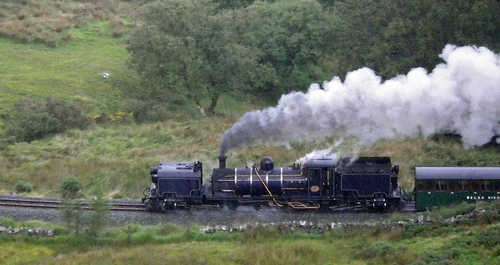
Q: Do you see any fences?
A: Yes, there is a fence.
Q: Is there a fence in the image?
A: Yes, there is a fence.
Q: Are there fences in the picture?
A: Yes, there is a fence.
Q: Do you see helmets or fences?
A: Yes, there is a fence.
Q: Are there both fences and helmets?
A: No, there is a fence but no helmets.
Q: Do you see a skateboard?
A: No, there are no skateboards.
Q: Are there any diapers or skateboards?
A: No, there are no skateboards or diapers.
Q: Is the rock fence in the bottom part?
A: Yes, the fence is in the bottom of the image.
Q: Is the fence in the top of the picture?
A: No, the fence is in the bottom of the image.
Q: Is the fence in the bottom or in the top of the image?
A: The fence is in the bottom of the image.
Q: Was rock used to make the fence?
A: Yes, the fence is made of rock.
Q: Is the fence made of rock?
A: Yes, the fence is made of rock.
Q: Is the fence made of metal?
A: No, the fence is made of rock.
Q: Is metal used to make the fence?
A: No, the fence is made of rock.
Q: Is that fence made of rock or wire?
A: The fence is made of rock.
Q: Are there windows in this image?
A: Yes, there are windows.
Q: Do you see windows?
A: Yes, there are windows.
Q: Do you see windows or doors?
A: Yes, there are windows.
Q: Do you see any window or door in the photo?
A: Yes, there are windows.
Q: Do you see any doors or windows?
A: Yes, there are windows.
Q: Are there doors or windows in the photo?
A: Yes, there are windows.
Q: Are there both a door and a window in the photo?
A: Yes, there are both a window and a door.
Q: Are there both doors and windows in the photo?
A: Yes, there are both windows and a door.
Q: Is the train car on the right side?
A: Yes, the train car is on the right of the image.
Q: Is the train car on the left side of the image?
A: No, the train car is on the right of the image.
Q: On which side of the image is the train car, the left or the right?
A: The train car is on the right of the image.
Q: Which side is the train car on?
A: The train car is on the right of the image.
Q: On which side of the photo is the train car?
A: The train car is on the right of the image.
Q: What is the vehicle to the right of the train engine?
A: The vehicle is a train car.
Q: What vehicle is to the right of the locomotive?
A: The vehicle is a train car.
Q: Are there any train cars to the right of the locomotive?
A: Yes, there is a train car to the right of the locomotive.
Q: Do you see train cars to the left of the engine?
A: No, the train car is to the right of the engine.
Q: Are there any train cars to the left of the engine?
A: No, the train car is to the right of the engine.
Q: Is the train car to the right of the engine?
A: Yes, the train car is to the right of the engine.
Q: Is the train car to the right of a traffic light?
A: No, the train car is to the right of the engine.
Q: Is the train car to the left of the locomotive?
A: No, the train car is to the right of the locomotive.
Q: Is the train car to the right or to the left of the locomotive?
A: The train car is to the right of the locomotive.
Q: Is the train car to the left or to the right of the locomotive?
A: The train car is to the right of the locomotive.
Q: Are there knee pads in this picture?
A: No, there are no knee pads.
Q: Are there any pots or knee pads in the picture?
A: No, there are no knee pads or pots.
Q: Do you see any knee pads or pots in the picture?
A: No, there are no knee pads or pots.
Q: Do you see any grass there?
A: Yes, there is grass.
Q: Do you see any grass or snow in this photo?
A: Yes, there is grass.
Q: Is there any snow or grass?
A: Yes, there is grass.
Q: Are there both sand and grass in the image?
A: No, there is grass but no sand.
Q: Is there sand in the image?
A: No, there is no sand.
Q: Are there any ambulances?
A: No, there are no ambulances.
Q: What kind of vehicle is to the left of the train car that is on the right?
A: The vehicle is a locomotive.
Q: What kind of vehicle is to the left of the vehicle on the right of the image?
A: The vehicle is a locomotive.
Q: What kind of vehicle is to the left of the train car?
A: The vehicle is a locomotive.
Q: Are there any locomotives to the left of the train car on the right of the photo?
A: Yes, there is a locomotive to the left of the train car.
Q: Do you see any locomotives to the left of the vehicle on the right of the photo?
A: Yes, there is a locomotive to the left of the train car.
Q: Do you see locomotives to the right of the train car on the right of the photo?
A: No, the locomotive is to the left of the train car.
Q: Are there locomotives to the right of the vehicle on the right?
A: No, the locomotive is to the left of the train car.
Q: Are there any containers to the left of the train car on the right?
A: No, there is a locomotive to the left of the train car.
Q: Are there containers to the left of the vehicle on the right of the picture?
A: No, there is a locomotive to the left of the train car.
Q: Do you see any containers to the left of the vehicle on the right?
A: No, there is a locomotive to the left of the train car.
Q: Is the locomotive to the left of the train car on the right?
A: Yes, the locomotive is to the left of the train car.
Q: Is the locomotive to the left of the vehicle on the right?
A: Yes, the locomotive is to the left of the train car.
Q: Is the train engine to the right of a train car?
A: No, the train engine is to the left of a train car.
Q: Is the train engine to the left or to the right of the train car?
A: The train engine is to the left of the train car.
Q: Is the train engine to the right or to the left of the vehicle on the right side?
A: The train engine is to the left of the train car.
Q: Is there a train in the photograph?
A: Yes, there is a train.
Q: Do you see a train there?
A: Yes, there is a train.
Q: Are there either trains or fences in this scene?
A: Yes, there is a train.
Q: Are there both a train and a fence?
A: Yes, there are both a train and a fence.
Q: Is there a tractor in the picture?
A: No, there are no tractors.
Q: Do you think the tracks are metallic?
A: Yes, the tracks are metallic.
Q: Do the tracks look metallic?
A: Yes, the tracks are metallic.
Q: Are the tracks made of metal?
A: Yes, the tracks are made of metal.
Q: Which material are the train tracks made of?
A: The train tracks are made of metal.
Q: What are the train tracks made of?
A: The train tracks are made of metal.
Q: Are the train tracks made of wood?
A: No, the train tracks are made of metal.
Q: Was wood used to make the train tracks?
A: No, the train tracks are made of metal.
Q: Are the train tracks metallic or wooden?
A: The train tracks are metallic.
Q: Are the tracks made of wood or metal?
A: The tracks are made of metal.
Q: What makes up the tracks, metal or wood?
A: The tracks are made of metal.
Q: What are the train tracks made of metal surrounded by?
A: The train tracks are surrounded by the gravel.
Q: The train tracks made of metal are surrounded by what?
A: The train tracks are surrounded by the gravel.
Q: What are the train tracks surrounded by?
A: The train tracks are surrounded by the gravel.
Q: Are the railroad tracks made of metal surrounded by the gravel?
A: Yes, the tracks are surrounded by the gravel.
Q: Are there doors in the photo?
A: Yes, there is a door.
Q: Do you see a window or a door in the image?
A: Yes, there is a door.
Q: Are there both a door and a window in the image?
A: Yes, there are both a door and a window.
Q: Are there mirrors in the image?
A: No, there are no mirrors.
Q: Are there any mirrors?
A: No, there are no mirrors.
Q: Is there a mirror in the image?
A: No, there are no mirrors.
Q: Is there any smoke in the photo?
A: Yes, there is smoke.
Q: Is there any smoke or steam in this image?
A: Yes, there is smoke.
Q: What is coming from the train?
A: The smoke is coming from the train.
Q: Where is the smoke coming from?
A: The smoke is coming from the train.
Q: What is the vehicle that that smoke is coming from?
A: The vehicle is a train.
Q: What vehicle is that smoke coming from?
A: The smoke is coming from the train.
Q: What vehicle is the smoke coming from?
A: The smoke is coming from the train.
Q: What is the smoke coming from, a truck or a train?
A: The smoke is coming from a train.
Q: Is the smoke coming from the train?
A: Yes, the smoke is coming from the train.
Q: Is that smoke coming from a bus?
A: No, the smoke is coming from the train.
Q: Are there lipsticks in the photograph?
A: No, there are no lipsticks.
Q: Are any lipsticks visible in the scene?
A: No, there are no lipsticks.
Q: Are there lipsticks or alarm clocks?
A: No, there are no lipsticks or alarm clocks.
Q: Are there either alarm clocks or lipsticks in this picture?
A: No, there are no lipsticks or alarm clocks.